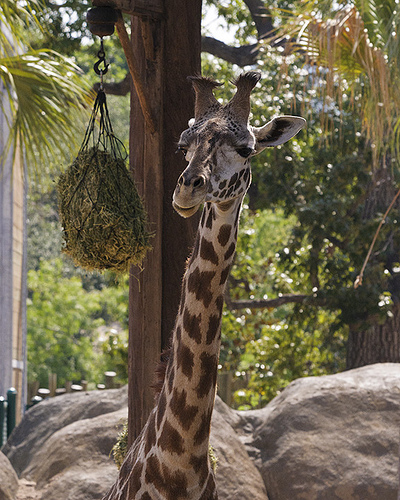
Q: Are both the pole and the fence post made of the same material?
A: No, the pole is made of wood and the fence post is made of metal.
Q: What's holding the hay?
A: The hook is holding the hay.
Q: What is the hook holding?
A: The hook is holding the hay.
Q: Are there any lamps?
A: No, there are no lamps.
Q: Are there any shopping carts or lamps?
A: No, there are no lamps or shopping carts.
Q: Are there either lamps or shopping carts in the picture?
A: No, there are no lamps or shopping carts.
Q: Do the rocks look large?
A: Yes, the rocks are large.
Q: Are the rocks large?
A: Yes, the rocks are large.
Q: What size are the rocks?
A: The rocks are large.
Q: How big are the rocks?
A: The rocks are large.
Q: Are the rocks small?
A: No, the rocks are large.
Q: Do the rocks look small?
A: No, the rocks are large.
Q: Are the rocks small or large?
A: The rocks are large.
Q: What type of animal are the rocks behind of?
A: The rocks are behind the giraffe.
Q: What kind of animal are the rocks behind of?
A: The rocks are behind the giraffe.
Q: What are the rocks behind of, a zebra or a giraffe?
A: The rocks are behind a giraffe.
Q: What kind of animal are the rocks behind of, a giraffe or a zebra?
A: The rocks are behind a giraffe.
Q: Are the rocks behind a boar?
A: No, the rocks are behind the giraffe.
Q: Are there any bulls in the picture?
A: No, there are no bulls.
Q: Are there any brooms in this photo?
A: No, there are no brooms.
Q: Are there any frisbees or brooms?
A: No, there are no brooms or frisbees.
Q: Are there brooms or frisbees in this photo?
A: No, there are no brooms or frisbees.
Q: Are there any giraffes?
A: Yes, there is a giraffe.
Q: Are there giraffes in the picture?
A: Yes, there is a giraffe.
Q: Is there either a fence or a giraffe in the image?
A: Yes, there is a giraffe.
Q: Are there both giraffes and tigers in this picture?
A: No, there is a giraffe but no tigers.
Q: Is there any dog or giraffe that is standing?
A: Yes, the giraffe is standing.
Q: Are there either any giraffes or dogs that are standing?
A: Yes, the giraffe is standing.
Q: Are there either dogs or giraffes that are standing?
A: Yes, the giraffe is standing.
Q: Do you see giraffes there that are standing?
A: Yes, there is a giraffe that is standing.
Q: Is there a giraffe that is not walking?
A: Yes, there is a giraffe that is standing.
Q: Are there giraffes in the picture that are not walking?
A: Yes, there is a giraffe that is standing.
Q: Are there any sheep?
A: No, there are no sheep.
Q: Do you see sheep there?
A: No, there are no sheep.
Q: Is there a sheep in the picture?
A: No, there is no sheep.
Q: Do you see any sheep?
A: No, there are no sheep.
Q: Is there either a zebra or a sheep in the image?
A: No, there are no sheep or zebras.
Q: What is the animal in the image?
A: The animal is a giraffe.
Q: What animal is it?
A: The animal is a giraffe.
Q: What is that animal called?
A: This is a giraffe.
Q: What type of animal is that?
A: This is a giraffe.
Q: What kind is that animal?
A: This is a giraffe.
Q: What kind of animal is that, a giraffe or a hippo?
A: This is a giraffe.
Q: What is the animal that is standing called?
A: The animal is a giraffe.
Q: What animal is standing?
A: The animal is a giraffe.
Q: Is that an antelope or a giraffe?
A: That is a giraffe.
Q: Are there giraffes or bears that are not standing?
A: No, there is a giraffe but it is standing.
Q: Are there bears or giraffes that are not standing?
A: No, there is a giraffe but it is standing.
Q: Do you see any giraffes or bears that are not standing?
A: No, there is a giraffe but it is standing.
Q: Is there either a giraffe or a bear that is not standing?
A: No, there is a giraffe but it is standing.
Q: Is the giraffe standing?
A: Yes, the giraffe is standing.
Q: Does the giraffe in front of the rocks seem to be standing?
A: Yes, the giraffe is standing.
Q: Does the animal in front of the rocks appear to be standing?
A: Yes, the giraffe is standing.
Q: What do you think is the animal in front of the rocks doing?
A: The giraffe is standing.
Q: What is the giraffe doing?
A: The giraffe is standing.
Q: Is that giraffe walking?
A: No, the giraffe is standing.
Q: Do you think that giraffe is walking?
A: No, the giraffe is standing.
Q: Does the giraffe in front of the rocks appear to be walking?
A: No, the giraffe is standing.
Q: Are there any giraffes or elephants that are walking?
A: No, there is a giraffe but it is standing.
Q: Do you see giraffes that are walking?
A: No, there is a giraffe but it is standing.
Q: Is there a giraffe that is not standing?
A: No, there is a giraffe but it is standing.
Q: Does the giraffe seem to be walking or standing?
A: The giraffe is standing.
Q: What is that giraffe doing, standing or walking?
A: The giraffe is standing.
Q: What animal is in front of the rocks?
A: The giraffe is in front of the rocks.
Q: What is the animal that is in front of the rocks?
A: The animal is a giraffe.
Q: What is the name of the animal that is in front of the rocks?
A: The animal is a giraffe.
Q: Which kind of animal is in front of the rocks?
A: The animal is a giraffe.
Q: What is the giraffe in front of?
A: The giraffe is in front of the rocks.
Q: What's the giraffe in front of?
A: The giraffe is in front of the rocks.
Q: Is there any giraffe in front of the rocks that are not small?
A: Yes, there is a giraffe in front of the rocks.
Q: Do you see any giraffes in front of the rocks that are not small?
A: Yes, there is a giraffe in front of the rocks.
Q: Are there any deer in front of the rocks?
A: No, there is a giraffe in front of the rocks.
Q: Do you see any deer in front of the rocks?
A: No, there is a giraffe in front of the rocks.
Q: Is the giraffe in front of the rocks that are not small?
A: Yes, the giraffe is in front of the rocks.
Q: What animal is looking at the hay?
A: The giraffe is looking at the hay.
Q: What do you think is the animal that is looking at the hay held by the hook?
A: The animal is a giraffe.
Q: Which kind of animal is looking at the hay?
A: The animal is a giraffe.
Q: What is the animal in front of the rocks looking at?
A: The giraffe is looking at the hay.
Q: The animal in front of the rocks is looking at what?
A: The giraffe is looking at the hay.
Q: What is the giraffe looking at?
A: The giraffe is looking at the hay.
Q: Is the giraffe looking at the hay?
A: Yes, the giraffe is looking at the hay.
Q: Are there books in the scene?
A: No, there are no books.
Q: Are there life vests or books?
A: No, there are no books or life vests.